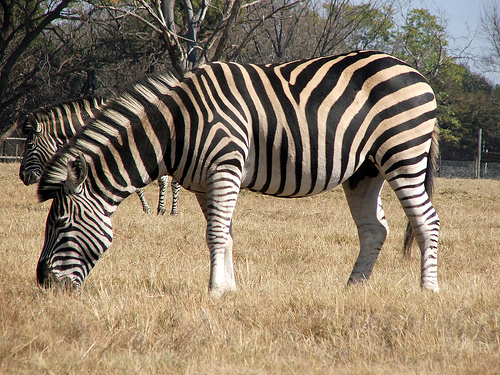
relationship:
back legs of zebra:
[341, 147, 451, 297] [35, 49, 440, 300]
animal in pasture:
[20, 94, 115, 186] [3, 6, 485, 369]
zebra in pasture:
[35, 49, 440, 300] [3, 6, 485, 369]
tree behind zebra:
[101, 0, 270, 80] [35, 49, 440, 300]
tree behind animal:
[101, 0, 270, 80] [19, 94, 181, 217]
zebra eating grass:
[35, 49, 440, 300] [5, 275, 498, 374]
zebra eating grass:
[35, 49, 440, 300] [12, 223, 492, 373]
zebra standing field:
[35, 49, 440, 300] [0, 160, 500, 373]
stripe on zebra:
[252, 61, 322, 197] [22, 71, 490, 316]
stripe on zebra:
[252, 61, 322, 197] [35, 49, 440, 300]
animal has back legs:
[19, 94, 181, 217] [341, 144, 441, 295]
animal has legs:
[19, 94, 181, 217] [152, 171, 172, 215]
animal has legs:
[19, 94, 181, 217] [200, 165, 242, 297]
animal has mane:
[19, 94, 181, 217] [35, 65, 187, 202]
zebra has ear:
[35, 49, 440, 300] [46, 137, 96, 181]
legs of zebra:
[197, 188, 241, 305] [29, 42, 452, 319]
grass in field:
[0, 161, 499, 373] [4, 146, 484, 365]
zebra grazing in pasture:
[35, 49, 440, 300] [2, 158, 496, 374]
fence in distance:
[0, 128, 500, 179] [0, 122, 498, 194]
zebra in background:
[20, 60, 498, 331] [7, 36, 498, 181]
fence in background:
[1, 134, 498, 179] [1, 2, 496, 178]